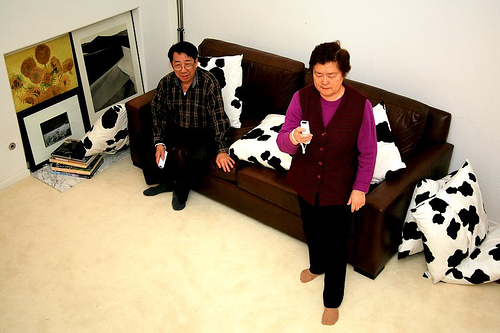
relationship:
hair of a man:
[308, 40, 351, 77] [275, 42, 374, 327]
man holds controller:
[143, 41, 236, 210] [158, 151, 168, 169]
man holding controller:
[107, 33, 244, 245] [129, 126, 187, 187]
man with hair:
[143, 41, 236, 210] [165, 40, 195, 56]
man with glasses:
[143, 41, 236, 210] [169, 57, 193, 71]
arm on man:
[346, 98, 377, 214] [275, 42, 374, 327]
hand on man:
[343, 185, 368, 214] [275, 42, 374, 327]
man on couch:
[143, 41, 236, 210] [121, 35, 455, 276]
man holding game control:
[275, 42, 374, 327] [295, 115, 315, 151]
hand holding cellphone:
[289, 125, 314, 145] [300, 120, 311, 144]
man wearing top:
[275, 42, 374, 327] [316, 97, 344, 122]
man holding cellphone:
[275, 42, 374, 327] [288, 115, 311, 142]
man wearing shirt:
[143, 41, 236, 210] [148, 59, 232, 158]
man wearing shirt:
[275, 42, 374, 327] [287, 84, 368, 205]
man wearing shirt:
[275, 42, 374, 327] [277, 84, 387, 195]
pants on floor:
[302, 192, 355, 307] [114, 236, 254, 313]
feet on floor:
[296, 258, 346, 327] [114, 236, 254, 313]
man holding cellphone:
[275, 42, 374, 327] [300, 120, 311, 144]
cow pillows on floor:
[443, 220, 499, 289] [7, 160, 490, 332]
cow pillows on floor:
[414, 149, 491, 285] [7, 160, 490, 332]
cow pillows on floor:
[392, 160, 459, 257] [7, 160, 490, 332]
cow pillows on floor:
[89, 92, 136, 162] [7, 160, 490, 332]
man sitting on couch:
[143, 41, 236, 210] [121, 35, 455, 276]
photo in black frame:
[34, 113, 75, 146] [4, 43, 114, 189]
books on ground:
[48, 133, 105, 183] [8, 205, 234, 326]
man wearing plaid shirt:
[143, 41, 236, 210] [153, 77, 232, 152]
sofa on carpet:
[113, 22, 455, 277] [9, 143, 498, 331]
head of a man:
[301, 32, 380, 107] [275, 42, 374, 327]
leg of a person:
[324, 216, 358, 327] [286, 40, 378, 325]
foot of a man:
[319, 291, 342, 323] [275, 42, 374, 327]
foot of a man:
[300, 266, 320, 283] [275, 42, 374, 327]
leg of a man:
[290, 199, 331, 289] [275, 42, 374, 327]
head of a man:
[166, 34, 204, 88] [143, 41, 236, 210]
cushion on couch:
[238, 104, 300, 175] [146, 32, 459, 272]